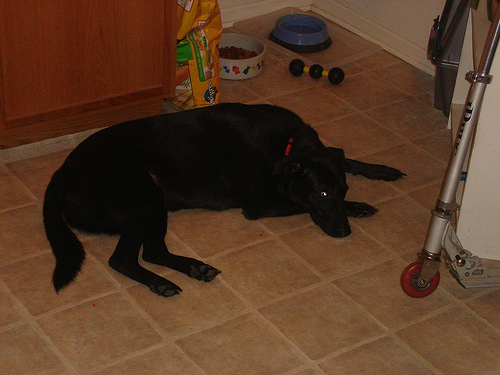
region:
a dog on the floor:
[51, 109, 403, 304]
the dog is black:
[46, 100, 408, 302]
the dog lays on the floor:
[51, 99, 410, 301]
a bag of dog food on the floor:
[175, 0, 223, 108]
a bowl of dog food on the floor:
[218, 36, 268, 84]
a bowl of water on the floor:
[273, 15, 335, 52]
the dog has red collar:
[285, 136, 295, 156]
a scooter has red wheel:
[408, 265, 440, 300]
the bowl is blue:
[276, 8, 331, 51]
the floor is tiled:
[0, 10, 499, 372]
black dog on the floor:
[31, 81, 416, 318]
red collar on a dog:
[277, 131, 304, 165]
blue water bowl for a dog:
[271, 4, 335, 62]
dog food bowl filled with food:
[213, 26, 270, 88]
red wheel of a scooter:
[400, 249, 440, 299]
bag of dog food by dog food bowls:
[177, 2, 223, 114]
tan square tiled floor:
[243, 243, 351, 374]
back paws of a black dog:
[147, 248, 225, 313]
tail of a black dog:
[40, 210, 90, 308]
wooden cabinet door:
[20, 13, 132, 96]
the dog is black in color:
[21, 89, 384, 284]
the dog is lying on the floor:
[58, 98, 408, 300]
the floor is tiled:
[230, 297, 393, 372]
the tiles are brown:
[262, 280, 399, 365]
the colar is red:
[268, 118, 300, 173]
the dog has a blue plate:
[275, 10, 338, 52]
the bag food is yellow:
[178, 1, 230, 100]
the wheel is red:
[396, 257, 442, 299]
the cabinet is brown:
[8, 13, 182, 110]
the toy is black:
[285, 56, 360, 87]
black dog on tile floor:
[53, 87, 350, 274]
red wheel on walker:
[401, 251, 444, 292]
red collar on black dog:
[265, 119, 317, 178]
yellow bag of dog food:
[168, 17, 236, 117]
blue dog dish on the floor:
[263, 13, 341, 67]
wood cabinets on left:
[5, 30, 196, 147]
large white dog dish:
[213, 37, 268, 87]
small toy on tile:
[284, 45, 334, 90]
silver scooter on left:
[404, 70, 496, 212]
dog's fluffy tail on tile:
[32, 174, 94, 310]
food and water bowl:
[205, 1, 346, 77]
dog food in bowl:
[205, 17, 282, 89]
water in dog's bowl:
[261, 3, 353, 70]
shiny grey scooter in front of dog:
[377, 0, 493, 324]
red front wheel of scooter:
[400, 250, 450, 307]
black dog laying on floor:
[11, 99, 391, 300]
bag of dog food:
[169, 0, 245, 120]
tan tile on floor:
[241, 288, 405, 363]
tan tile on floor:
[199, 234, 336, 306]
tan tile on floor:
[49, 296, 173, 368]